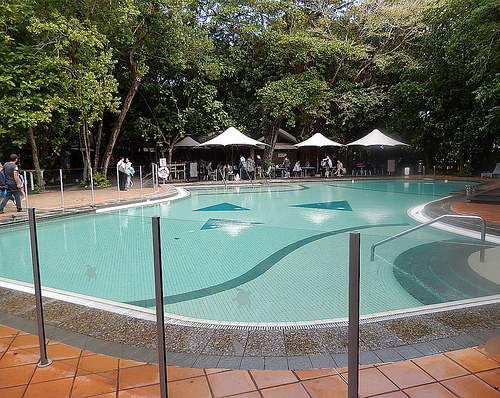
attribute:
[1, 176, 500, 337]
pool — outdoors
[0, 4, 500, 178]
trees — green